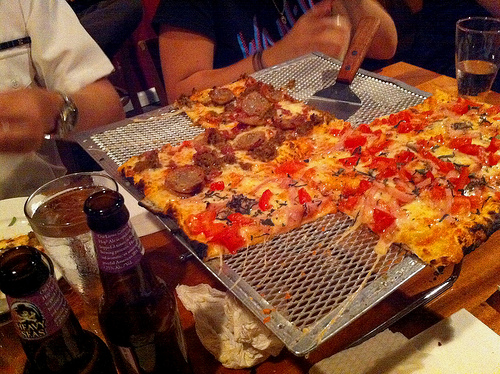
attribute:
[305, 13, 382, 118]
spatula — wooden, handled, pizza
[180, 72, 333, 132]
pizza — slice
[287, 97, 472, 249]
pizza — cheesy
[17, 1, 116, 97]
sleeve — man's, white, shirt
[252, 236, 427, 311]
screen — pizza, aluminum